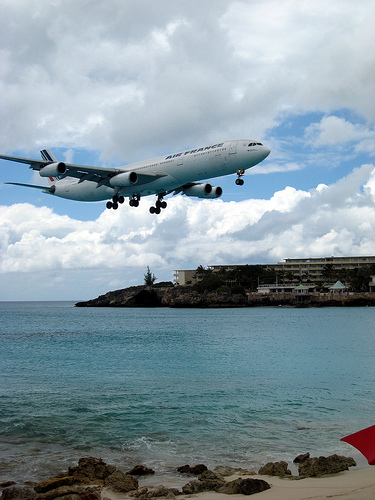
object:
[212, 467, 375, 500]
sand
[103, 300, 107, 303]
rocks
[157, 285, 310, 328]
shore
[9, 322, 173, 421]
water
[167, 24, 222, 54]
cloud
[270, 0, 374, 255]
sky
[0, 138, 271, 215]
airplane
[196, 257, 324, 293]
building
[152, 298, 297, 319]
ledge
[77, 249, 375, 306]
land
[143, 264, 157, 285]
tree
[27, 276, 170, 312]
edge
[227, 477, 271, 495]
stone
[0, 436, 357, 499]
beach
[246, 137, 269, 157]
nose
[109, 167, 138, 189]
engine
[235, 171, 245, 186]
landing gear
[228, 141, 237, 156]
door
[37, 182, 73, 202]
tail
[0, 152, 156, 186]
wing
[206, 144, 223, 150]
writing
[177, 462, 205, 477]
rock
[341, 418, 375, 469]
umbrella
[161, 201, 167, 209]
wheels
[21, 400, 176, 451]
wave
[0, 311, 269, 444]
ocean